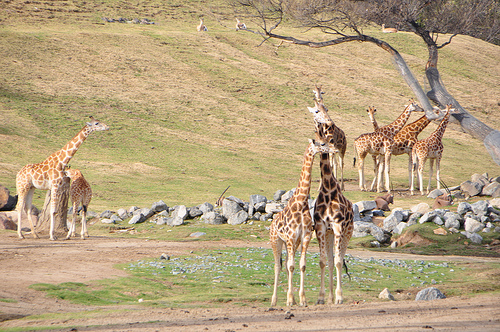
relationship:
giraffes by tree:
[274, 122, 342, 301] [384, 31, 499, 149]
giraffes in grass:
[274, 122, 342, 301] [173, 244, 442, 300]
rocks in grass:
[119, 191, 473, 243] [173, 244, 442, 300]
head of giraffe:
[83, 110, 114, 133] [11, 112, 106, 252]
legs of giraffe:
[8, 188, 80, 241] [11, 112, 106, 252]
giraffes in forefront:
[274, 122, 342, 301] [10, 224, 482, 324]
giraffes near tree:
[274, 122, 342, 301] [384, 31, 499, 149]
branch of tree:
[375, 49, 436, 114] [384, 31, 499, 149]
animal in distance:
[187, 18, 222, 35] [3, 6, 495, 144]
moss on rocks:
[366, 206, 497, 259] [119, 191, 473, 243]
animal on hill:
[187, 18, 222, 35] [8, 7, 456, 171]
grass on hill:
[173, 244, 442, 300] [8, 7, 456, 171]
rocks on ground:
[119, 191, 473, 243] [26, 223, 481, 327]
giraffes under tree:
[274, 122, 342, 301] [384, 31, 499, 149]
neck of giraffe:
[56, 129, 89, 164] [11, 112, 106, 252]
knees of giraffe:
[15, 208, 64, 219] [11, 112, 106, 252]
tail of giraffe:
[10, 166, 21, 190] [11, 112, 106, 252]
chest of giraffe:
[50, 163, 83, 193] [11, 112, 106, 252]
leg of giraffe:
[46, 187, 67, 239] [11, 112, 106, 252]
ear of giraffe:
[83, 113, 91, 128] [11, 112, 106, 252]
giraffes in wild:
[274, 122, 342, 301] [5, 6, 477, 330]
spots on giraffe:
[316, 192, 351, 221] [11, 112, 106, 252]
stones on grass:
[230, 184, 492, 213] [173, 244, 442, 300]